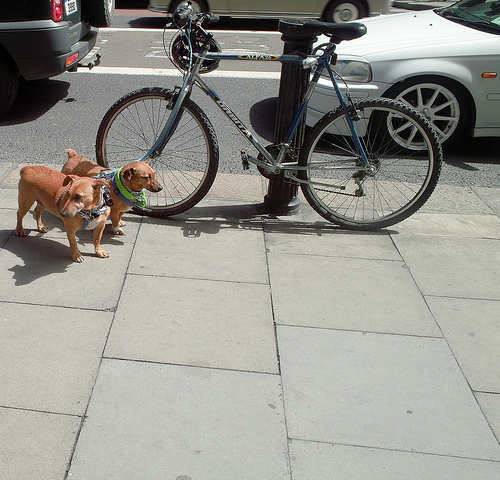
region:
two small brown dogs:
[7, 146, 176, 277]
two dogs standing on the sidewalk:
[11, 138, 173, 273]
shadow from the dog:
[0, 220, 82, 297]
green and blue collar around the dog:
[104, 163, 157, 220]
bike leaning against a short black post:
[98, 6, 458, 251]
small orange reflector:
[477, 70, 498, 83]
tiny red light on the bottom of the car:
[62, 50, 89, 71]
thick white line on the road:
[87, 55, 290, 102]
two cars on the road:
[2, 1, 499, 179]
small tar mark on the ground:
[400, 407, 420, 419]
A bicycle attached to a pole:
[93, 4, 443, 234]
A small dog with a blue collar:
[14, 165, 111, 255]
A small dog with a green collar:
[64, 145, 162, 232]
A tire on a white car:
[383, 74, 465, 153]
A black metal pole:
[262, 17, 320, 214]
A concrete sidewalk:
[2, 191, 499, 478]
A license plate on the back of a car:
[65, 0, 75, 15]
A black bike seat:
[303, 18, 365, 41]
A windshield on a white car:
[433, 0, 498, 36]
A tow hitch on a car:
[93, 51, 105, 65]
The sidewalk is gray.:
[1, 163, 496, 478]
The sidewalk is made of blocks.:
[0, 162, 498, 477]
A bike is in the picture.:
[93, 0, 444, 237]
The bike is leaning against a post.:
[95, 4, 442, 231]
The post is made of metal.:
[263, 13, 322, 210]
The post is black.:
[262, 15, 322, 212]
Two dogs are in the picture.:
[11, 148, 163, 262]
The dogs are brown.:
[8, 145, 163, 261]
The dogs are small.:
[12, 148, 165, 260]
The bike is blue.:
[93, 3, 443, 230]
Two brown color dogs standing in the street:
[0, 135, 170, 260]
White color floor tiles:
[133, 293, 404, 422]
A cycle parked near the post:
[138, 68, 445, 200]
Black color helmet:
[157, 31, 226, 76]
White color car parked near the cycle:
[325, 12, 499, 138]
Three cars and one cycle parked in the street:
[5, 0, 498, 133]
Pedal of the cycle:
[232, 147, 255, 172]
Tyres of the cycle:
[124, 92, 442, 237]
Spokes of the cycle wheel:
[381, 130, 412, 192]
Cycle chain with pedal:
[237, 147, 364, 204]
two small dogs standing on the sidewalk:
[14, 145, 163, 263]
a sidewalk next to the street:
[1, 203, 499, 478]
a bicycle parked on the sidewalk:
[93, 0, 443, 230]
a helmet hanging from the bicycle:
[169, 30, 220, 73]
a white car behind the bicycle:
[305, 0, 499, 153]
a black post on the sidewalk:
[266, 7, 324, 212]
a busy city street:
[0, 13, 499, 187]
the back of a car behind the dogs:
[0, 0, 114, 88]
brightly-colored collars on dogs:
[73, 166, 146, 234]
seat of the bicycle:
[302, 18, 367, 42]